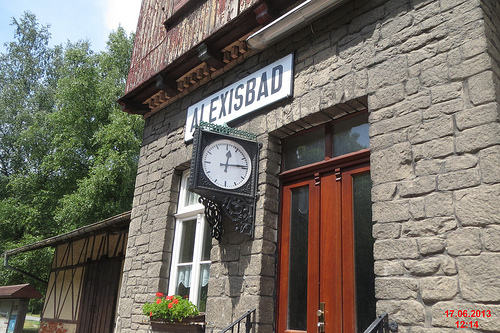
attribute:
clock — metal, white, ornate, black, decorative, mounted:
[201, 139, 252, 187]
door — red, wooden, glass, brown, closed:
[274, 108, 377, 332]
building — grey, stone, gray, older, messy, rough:
[114, 0, 499, 332]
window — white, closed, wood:
[161, 162, 208, 318]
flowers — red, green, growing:
[141, 291, 198, 322]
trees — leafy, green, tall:
[0, 8, 145, 315]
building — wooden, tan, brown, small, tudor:
[3, 209, 133, 332]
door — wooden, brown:
[74, 255, 124, 332]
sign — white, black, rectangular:
[184, 50, 293, 142]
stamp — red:
[445, 308, 493, 328]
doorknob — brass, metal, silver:
[317, 300, 325, 331]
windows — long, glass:
[287, 169, 373, 332]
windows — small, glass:
[279, 108, 369, 175]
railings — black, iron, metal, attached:
[217, 306, 389, 332]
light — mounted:
[247, 0, 341, 50]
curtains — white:
[177, 265, 209, 287]